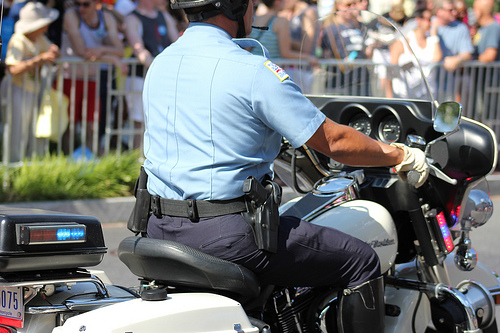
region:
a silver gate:
[10, 61, 497, 183]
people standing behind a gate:
[3, 3, 495, 81]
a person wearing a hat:
[11, 4, 53, 102]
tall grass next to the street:
[3, 154, 138, 191]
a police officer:
[129, 1, 421, 308]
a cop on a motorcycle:
[65, 3, 495, 318]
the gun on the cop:
[239, 172, 283, 250]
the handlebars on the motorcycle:
[264, 125, 437, 193]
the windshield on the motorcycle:
[296, 10, 430, 100]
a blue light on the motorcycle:
[30, 227, 90, 241]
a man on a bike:
[68, 43, 403, 318]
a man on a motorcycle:
[115, 74, 411, 322]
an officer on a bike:
[76, 6, 469, 321]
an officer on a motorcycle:
[76, 71, 405, 328]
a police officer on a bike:
[123, 43, 440, 330]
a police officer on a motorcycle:
[62, 49, 492, 316]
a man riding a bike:
[76, 27, 481, 299]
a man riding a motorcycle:
[99, 4, 485, 315]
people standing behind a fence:
[30, 6, 497, 201]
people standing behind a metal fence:
[18, 4, 438, 138]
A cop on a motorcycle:
[126, 2, 388, 332]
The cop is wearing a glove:
[397, 138, 425, 187]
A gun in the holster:
[243, 177, 280, 248]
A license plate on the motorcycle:
[0, 284, 21, 314]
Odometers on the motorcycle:
[343, 111, 401, 141]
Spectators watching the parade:
[1, 2, 498, 161]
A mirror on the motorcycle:
[433, 99, 463, 131]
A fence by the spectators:
[1, 59, 499, 164]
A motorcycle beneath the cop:
[1, 5, 488, 331]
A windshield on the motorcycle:
[298, 10, 433, 121]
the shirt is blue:
[146, 34, 359, 184]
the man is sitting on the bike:
[120, 21, 454, 324]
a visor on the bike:
[286, 41, 489, 210]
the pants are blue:
[207, 210, 404, 309]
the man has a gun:
[220, 155, 332, 309]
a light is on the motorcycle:
[7, 198, 97, 264]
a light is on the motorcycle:
[410, 87, 498, 171]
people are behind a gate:
[11, 38, 195, 211]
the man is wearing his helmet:
[167, 1, 267, 32]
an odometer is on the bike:
[331, 93, 450, 166]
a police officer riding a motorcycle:
[125, 1, 386, 328]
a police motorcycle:
[5, 13, 495, 330]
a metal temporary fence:
[5, 58, 492, 171]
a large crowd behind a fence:
[2, 2, 498, 149]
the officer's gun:
[246, 178, 281, 248]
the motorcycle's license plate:
[2, 288, 24, 323]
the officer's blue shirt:
[140, 29, 325, 199]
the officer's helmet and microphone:
[170, 0, 270, 41]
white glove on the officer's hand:
[393, 143, 429, 186]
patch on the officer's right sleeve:
[264, 61, 291, 81]